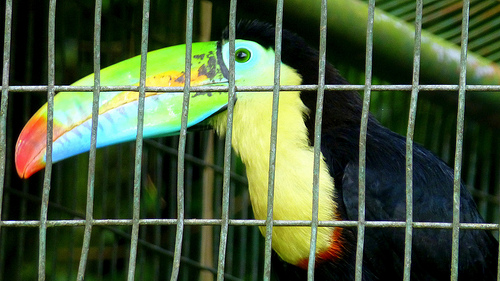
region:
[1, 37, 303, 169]
head of a bird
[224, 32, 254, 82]
eye of a bird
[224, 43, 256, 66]
an eye of a bird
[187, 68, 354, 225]
neck of a bird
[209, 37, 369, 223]
a neck of a bird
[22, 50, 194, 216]
mouth of a bird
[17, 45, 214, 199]
a mouth of a bird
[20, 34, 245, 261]
peck of a bird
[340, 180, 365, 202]
feather of a bird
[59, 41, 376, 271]
a bird in a cage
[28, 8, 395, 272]
a bird in a metal cage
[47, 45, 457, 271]
a bird in a sivler cage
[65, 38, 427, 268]
a silver metal cage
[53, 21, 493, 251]
a large bird on a cage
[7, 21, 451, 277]
a large bird in a metal cage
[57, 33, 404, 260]
a large bird in a silver cage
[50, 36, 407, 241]
a bird with a large beak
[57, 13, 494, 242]
a bird with a colorful beak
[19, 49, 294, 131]
a colorful beak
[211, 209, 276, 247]
the cage is gray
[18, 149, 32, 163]
the beck is red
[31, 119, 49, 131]
the beck is orange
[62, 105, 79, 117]
the beck is blue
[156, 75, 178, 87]
the beck is yellow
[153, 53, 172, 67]
the beck is green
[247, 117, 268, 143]
the bird is yellow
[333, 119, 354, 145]
the bird is black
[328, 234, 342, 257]
the bird is red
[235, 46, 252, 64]
the eye is green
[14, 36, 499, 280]
a toucan bird from the Amazon rain forest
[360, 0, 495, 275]
a wire fence for the bird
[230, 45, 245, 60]
the green and black eyes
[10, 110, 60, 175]
the red color of the beak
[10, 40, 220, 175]
the Toucans colorful beak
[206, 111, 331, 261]
the Toucans yellow feathers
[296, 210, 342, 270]
the red feathers on the Toucans body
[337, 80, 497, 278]
the black feathers of the Toucan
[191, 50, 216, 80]
the chipped area of the beak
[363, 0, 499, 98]
a pipe above the cage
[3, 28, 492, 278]
the toucan is in cage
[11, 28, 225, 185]
peak of toucan is long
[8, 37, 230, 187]
peak of tucan is green, blue and red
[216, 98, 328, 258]
breast of tucan is yellow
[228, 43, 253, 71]
eye of toucan is round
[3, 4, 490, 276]
cage of tucan is metal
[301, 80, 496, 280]
body of toucan is black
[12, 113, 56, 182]
tip of the beak is red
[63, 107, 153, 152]
part of the beak is blue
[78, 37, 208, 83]
part of the beak is green